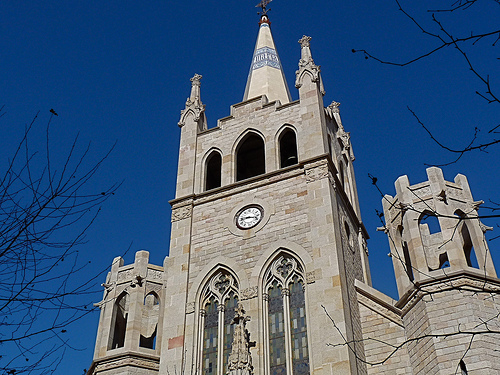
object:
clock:
[233, 204, 264, 230]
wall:
[357, 284, 415, 374]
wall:
[355, 288, 418, 374]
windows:
[199, 145, 226, 194]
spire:
[240, 0, 292, 110]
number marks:
[242, 222, 248, 228]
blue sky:
[0, 0, 500, 374]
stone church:
[80, 0, 500, 374]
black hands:
[243, 215, 256, 220]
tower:
[157, 0, 376, 374]